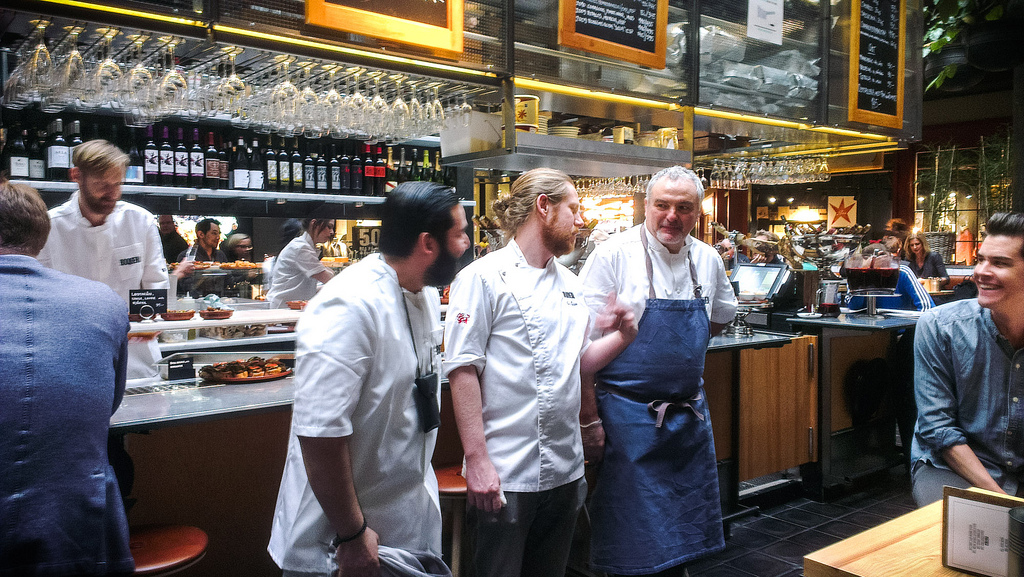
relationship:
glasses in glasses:
[35, 31, 208, 93] [0, 19, 473, 146]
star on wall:
[795, 169, 857, 225] [768, 147, 906, 253]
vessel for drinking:
[164, 255, 258, 323] [113, 130, 224, 198]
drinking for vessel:
[113, 130, 224, 198] [164, 255, 258, 323]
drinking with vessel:
[113, 130, 224, 198] [164, 255, 258, 323]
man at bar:
[7, 187, 129, 519] [88, 295, 334, 408]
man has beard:
[323, 166, 503, 576] [410, 231, 485, 283]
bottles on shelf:
[139, 112, 403, 193] [161, 142, 449, 215]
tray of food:
[190, 357, 311, 414] [215, 347, 283, 382]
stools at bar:
[128, 502, 322, 574] [88, 295, 334, 408]